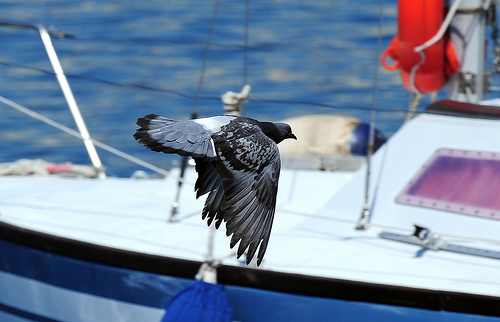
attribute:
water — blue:
[0, 0, 499, 176]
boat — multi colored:
[1, 0, 500, 321]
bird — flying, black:
[135, 113, 298, 267]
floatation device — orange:
[382, 0, 460, 95]